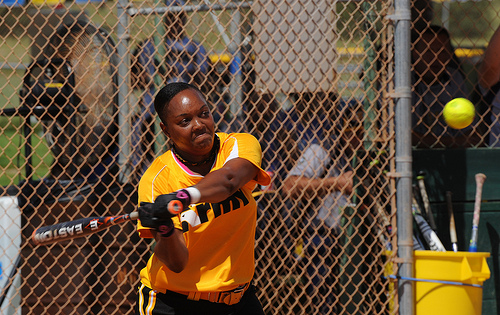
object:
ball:
[443, 97, 477, 130]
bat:
[32, 211, 138, 245]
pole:
[393, 0, 415, 315]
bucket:
[383, 250, 490, 315]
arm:
[187, 157, 261, 203]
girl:
[135, 82, 260, 314]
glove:
[140, 188, 192, 219]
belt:
[174, 281, 251, 305]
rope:
[384, 274, 484, 289]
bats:
[468, 173, 486, 252]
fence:
[0, 0, 411, 315]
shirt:
[286, 135, 350, 226]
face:
[164, 89, 214, 155]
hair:
[153, 82, 207, 126]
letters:
[34, 219, 99, 242]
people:
[128, 9, 210, 163]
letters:
[179, 189, 250, 233]